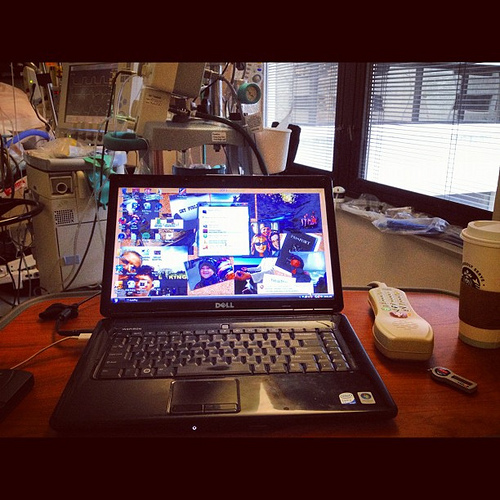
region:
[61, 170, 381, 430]
a black laptop computer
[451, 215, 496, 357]
a plastic coffee cup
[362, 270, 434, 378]
a hospital bed controller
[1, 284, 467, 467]
a bed side table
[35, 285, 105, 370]
cables and wires plugged into a laptop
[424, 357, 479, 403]
a computer flash drive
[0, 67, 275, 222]
hospital equipment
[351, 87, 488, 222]
a window with a blind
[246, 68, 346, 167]
a window with a open blind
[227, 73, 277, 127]
a gauge on a hospital equipment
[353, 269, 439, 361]
a white remote control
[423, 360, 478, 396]
a portable USB drive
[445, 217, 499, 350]
a foam cup of coffee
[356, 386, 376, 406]
Microsoft Windows logo sticker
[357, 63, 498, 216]
a window with venetian blinds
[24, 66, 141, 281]
hospital medical equipment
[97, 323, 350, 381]
black laptop computer keyboard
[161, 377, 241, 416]
computer track pad and buttons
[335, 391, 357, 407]
an Intel logo sticker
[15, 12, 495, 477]
A hospital room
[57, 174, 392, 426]
A black Dell laptop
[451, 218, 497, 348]
A drinking cup with a lid from starbucks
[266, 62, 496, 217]
Two windows with blinds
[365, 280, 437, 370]
A white hospital remote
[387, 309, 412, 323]
A red call button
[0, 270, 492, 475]
An adjustable rolling bed table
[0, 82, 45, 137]
A pillow with a white case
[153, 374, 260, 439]
A laptop touch pad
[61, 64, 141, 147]
A heart monitor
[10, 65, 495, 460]
laptop in a room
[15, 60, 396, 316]
lots of mechanical parts in the background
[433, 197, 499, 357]
a cup of coffee on the side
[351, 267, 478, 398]
a remote on the desk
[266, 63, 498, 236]
sunny dat outside the window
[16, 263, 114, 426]
wires connected to a laptop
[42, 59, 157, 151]
an old computer monitor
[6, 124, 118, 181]
a blue cable in the junk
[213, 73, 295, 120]
a green knob or meter reader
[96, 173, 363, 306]
a homescreen on a laptop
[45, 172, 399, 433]
black dell laptop computer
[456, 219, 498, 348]
a white coffee container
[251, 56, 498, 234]
a window with shutters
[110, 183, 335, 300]
a computer screen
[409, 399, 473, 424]
a wooden desk or table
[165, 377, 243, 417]
a small keypad on computer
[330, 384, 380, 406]
small stickers on laptop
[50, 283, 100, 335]
a black lapto cord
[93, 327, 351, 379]
a small keyboard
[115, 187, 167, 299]
icons on laptop screen